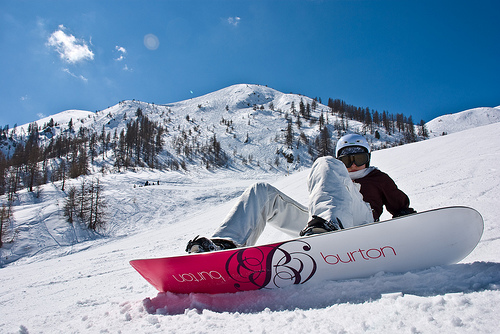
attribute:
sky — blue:
[0, 3, 487, 138]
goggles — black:
[341, 147, 368, 167]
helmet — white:
[333, 132, 372, 179]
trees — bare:
[13, 93, 176, 242]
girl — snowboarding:
[144, 147, 494, 289]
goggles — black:
[338, 154, 368, 167]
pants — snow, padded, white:
[203, 154, 377, 242]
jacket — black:
[300, 140, 430, 217]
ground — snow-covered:
[9, 167, 498, 329]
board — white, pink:
[77, 192, 459, 306]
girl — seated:
[173, 126, 415, 258]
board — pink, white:
[130, 205, 488, 299]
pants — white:
[227, 160, 368, 244]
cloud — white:
[35, 24, 114, 82]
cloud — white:
[42, 21, 112, 84]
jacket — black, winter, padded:
[355, 167, 412, 220]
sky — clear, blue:
[0, 0, 497, 80]